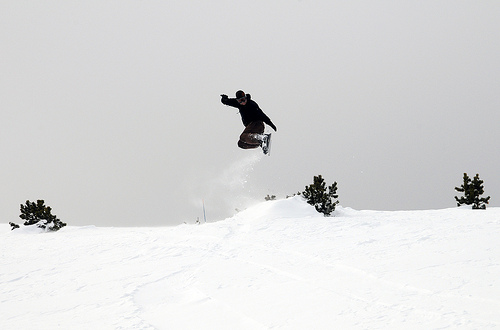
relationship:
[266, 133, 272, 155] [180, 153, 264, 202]
board kicking up snow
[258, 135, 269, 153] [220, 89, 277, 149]
boots on man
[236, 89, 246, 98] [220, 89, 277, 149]
cap on man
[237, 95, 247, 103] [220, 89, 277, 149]
googles on man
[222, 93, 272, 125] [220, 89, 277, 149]
jacket on man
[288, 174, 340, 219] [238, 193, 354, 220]
bush in snow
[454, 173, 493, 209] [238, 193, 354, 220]
bush in snow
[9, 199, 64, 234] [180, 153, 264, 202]
bush in snow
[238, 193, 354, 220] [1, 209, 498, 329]
snow on hill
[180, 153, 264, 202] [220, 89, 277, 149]
snow under man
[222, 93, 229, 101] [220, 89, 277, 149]
hand on man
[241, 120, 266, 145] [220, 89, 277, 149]
leg on man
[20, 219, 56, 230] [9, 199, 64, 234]
snow on bush